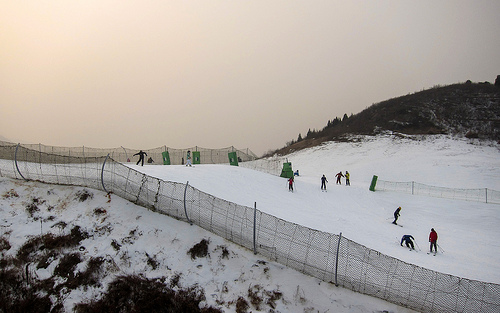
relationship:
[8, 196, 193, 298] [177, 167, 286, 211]
plants covered snow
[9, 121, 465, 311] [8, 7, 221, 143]
view taken sunset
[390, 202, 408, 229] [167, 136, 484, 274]
man skiing field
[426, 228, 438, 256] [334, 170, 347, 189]
person with arms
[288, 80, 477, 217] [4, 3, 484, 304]
hill on picture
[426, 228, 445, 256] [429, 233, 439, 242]
person with coat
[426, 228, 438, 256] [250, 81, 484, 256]
person standing hill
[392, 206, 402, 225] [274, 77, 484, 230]
man getting up hill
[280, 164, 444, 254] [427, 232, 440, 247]
skier wearing suit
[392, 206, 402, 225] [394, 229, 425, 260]
man attempting ski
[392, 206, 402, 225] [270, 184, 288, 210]
man walking snow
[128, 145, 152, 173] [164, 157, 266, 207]
person on hill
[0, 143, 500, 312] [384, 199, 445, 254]
fence enclosing people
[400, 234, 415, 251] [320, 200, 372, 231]
people in snow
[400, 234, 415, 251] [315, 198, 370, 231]
people in snow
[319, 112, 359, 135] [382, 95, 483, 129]
trees on hill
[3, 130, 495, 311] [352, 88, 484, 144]
snow on hill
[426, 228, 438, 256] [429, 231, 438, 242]
person in coat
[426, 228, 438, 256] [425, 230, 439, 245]
person in jacket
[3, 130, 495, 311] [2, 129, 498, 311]
snow on ground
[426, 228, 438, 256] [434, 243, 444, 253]
person holding poles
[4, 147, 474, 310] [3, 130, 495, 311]
fence in snow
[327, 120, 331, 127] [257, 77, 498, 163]
tree on mountain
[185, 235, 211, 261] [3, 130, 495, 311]
rock on snow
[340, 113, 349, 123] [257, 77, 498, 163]
tree on mountain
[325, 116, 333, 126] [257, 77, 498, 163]
tree on mountain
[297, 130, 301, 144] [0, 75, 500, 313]
tree on hill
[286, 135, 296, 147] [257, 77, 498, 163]
tree on mountain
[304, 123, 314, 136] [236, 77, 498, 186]
tree on mountain